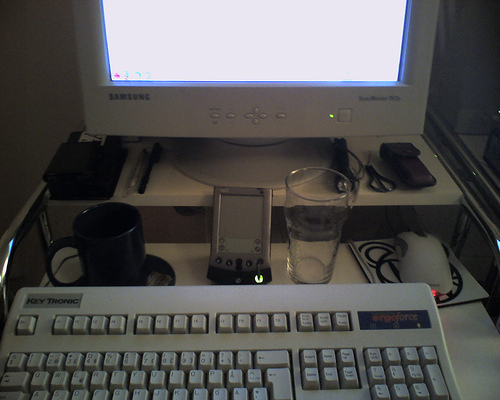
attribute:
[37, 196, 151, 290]
mug — black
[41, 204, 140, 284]
mug — black 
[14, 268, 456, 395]
keyboard — off white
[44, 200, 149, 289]
mug — black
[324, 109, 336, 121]
power light — green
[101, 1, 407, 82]
screen — blank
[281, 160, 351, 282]
glass — empty 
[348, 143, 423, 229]
scissors — black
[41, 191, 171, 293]
coffee mug — ceramic, black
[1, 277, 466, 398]
keyboard — white , computer, gray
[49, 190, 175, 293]
mug — coffee, black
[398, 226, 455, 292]
mouse — gray, two tones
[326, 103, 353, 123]
button — lit, power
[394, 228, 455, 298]
mouse — white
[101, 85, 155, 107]
samsung — black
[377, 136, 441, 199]
leatherman case — brown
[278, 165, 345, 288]
glass — empty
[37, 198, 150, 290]
cup — empty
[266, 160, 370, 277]
glass — water, clear